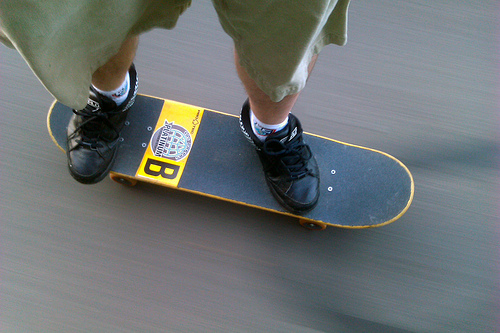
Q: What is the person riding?
A: Skateboard.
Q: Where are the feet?
A: On the skateboard.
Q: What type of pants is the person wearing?
A: Shorts.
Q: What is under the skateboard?
A: Road.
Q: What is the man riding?
A: A skateboard.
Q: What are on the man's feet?
A: Shoes and socks.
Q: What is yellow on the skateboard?
A: A sticker.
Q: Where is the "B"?
A: On the yellow sticker.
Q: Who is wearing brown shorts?
A: The man.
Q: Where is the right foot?
A: Near the back of the skateboard.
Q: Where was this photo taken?
A: Outside on the street.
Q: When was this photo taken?
A: During the day.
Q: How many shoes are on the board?
A: Two.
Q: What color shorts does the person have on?
A: Khaki.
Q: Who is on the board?
A: A skater.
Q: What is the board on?
A: The street.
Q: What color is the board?
A: Black and yellow.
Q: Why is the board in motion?
A: The person is skating.